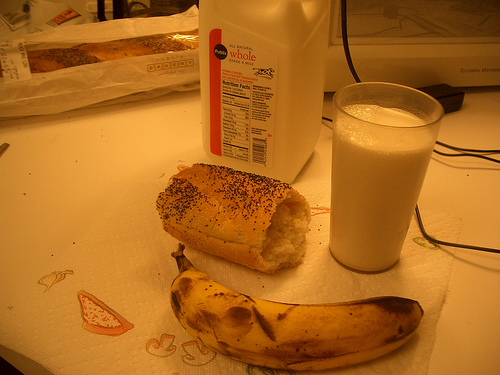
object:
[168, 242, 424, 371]
banana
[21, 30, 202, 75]
bread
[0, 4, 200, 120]
bag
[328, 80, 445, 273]
glass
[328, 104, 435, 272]
milk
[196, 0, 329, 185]
container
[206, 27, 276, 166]
label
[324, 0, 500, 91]
microwave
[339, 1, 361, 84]
cord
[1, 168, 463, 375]
tissue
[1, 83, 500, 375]
table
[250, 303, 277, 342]
bruise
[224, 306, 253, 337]
bruise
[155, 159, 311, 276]
bread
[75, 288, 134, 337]
picture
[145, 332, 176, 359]
picture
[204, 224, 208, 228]
seed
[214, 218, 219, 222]
seed